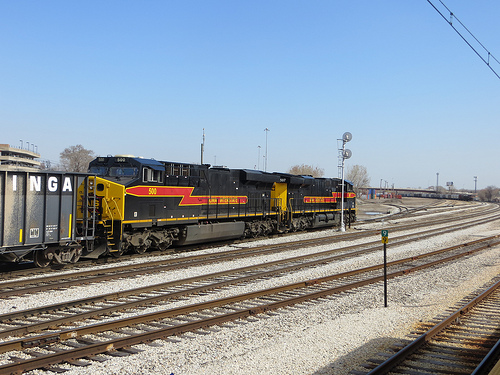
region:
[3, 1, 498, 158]
The sky is clear blue.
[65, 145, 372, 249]
The train is on the tracks.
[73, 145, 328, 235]
The train is black.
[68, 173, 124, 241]
The front of the train is yellow.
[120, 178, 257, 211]
The side has a red stripe.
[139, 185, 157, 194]
The numbers are yellow.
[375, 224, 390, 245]
The sign is green.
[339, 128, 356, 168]
The lights are off.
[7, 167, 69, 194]
The letters are white.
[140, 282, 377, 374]
The ground is rocky.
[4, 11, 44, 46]
white clouds in blue sky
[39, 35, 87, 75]
white clouds in blue sky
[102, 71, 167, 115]
white clouds in blue sky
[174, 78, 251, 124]
white clouds in blue sky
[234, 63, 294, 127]
white clouds in blue sky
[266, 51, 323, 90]
white clouds in blue sky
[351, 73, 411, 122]
white clouds in blue sky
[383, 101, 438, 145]
white clouds in blue sky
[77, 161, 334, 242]
black red and yellow train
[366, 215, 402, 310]
a pole in the rocks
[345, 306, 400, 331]
the gravel is white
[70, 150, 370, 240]
the train is parked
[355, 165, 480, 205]
train in the background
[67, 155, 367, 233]
the train is black and yellow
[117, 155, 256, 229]
a red zig zag on the side of the train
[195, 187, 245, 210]
the letters are yellow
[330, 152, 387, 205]
the tree is bare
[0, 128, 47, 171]
a building in the background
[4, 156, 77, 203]
the letters are white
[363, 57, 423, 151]
There is blue sky that is in the distance.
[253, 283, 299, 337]
There are brown railroad tracks that are visible.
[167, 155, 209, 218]
There is a train that has a red stripe on it.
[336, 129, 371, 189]
There is a light that is visible in the photo.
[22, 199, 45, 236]
There is a grey train car in the photo.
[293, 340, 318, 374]
There is white gravel visible in the photo.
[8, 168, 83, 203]
There are the letters "INGA" on the train.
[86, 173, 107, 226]
There is a yellow front to the train car.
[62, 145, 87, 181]
There are green trees that are in the distance.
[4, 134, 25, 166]
There are layers that are visible in the distance.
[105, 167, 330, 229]
black orange and yellow train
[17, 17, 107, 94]
white clouds in blue sky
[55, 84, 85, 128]
white clouds in blue sky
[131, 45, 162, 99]
white clouds in blue sky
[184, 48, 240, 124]
white clouds in blue sky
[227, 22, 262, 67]
white clouds in blue sky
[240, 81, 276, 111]
white clouds in blue sky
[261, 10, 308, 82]
white clouds in blue sky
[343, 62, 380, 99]
white clouds in blue sky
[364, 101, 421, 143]
white clouds in blue sky